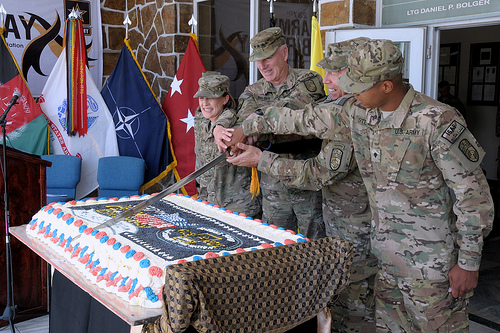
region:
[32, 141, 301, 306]
a cake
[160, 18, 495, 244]
people are cutting cake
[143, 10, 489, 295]
the people are soldiers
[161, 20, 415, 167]
soldiers wearing army hats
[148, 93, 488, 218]
soldiers wearing army uniforms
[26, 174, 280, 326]
the cake is pirmarily white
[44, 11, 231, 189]
flags beside the soldiers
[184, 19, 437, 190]
soldiers holding large knife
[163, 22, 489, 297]
soldiers' uniforms are green and brown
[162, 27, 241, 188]
the flag is red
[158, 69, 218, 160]
flag has white stars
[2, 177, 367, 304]
Large, rectangular cake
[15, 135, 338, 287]
Cake being cut with a sword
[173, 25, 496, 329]
Four service people in uniform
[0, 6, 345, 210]
Flags behind the people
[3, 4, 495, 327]
Photo taken during the day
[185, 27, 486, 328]
Four people in the picture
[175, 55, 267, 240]
One woman with the men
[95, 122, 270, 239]
A sword for cutting the cake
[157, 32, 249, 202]
Red flag with white stars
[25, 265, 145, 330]
Blue tablecloth under the cake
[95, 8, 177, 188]
blue and white star flag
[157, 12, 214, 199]
red and white star flag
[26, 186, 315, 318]
extra large cake on table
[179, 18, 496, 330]
four military personnel cutting a cake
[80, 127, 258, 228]
military sword being used to cut cake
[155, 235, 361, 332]
fabric wrapped around chair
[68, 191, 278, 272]
military-theme pattern on cake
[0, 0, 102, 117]
black, white, and yellow sign behind flags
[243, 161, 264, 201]
yellow tassel hanging from sword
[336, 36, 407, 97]
digital camoflage hat on man in front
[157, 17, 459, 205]
four army service people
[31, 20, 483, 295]
four uniformed service people cutting a cake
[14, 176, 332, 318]
a large sheet cake being cut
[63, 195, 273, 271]
cake with patriotic emblems as decorations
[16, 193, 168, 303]
red white and blue frosting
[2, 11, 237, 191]
a row of flags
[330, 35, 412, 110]
baseball cap with camoflage print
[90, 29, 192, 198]
dark blue flag with white emblem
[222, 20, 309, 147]
army officer laughing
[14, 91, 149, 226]
two blue chairs in front of flags